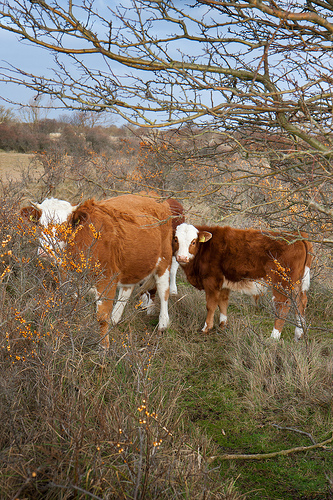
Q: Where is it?
A: This is at the field.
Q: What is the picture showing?
A: It is showing a field.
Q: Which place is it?
A: It is a field.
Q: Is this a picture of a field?
A: Yes, it is showing a field.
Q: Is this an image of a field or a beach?
A: It is showing a field.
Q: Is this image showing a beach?
A: No, the picture is showing a field.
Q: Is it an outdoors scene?
A: Yes, it is outdoors.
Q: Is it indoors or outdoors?
A: It is outdoors.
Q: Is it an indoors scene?
A: No, it is outdoors.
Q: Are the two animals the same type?
A: Yes, all the animals are cows.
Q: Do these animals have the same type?
A: Yes, all the animals are cows.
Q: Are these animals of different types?
A: No, all the animals are cows.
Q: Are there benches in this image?
A: No, there are no benches.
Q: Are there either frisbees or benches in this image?
A: No, there are no benches or frisbees.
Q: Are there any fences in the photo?
A: No, there are no fences.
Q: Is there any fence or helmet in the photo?
A: No, there are no fences or helmets.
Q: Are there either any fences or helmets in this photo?
A: No, there are no fences or helmets.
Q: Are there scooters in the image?
A: No, there are no scooters.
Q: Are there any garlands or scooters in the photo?
A: No, there are no scooters or garlands.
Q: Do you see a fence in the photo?
A: No, there are no fences.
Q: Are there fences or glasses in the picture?
A: No, there are no fences or glasses.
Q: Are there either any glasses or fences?
A: No, there are no fences or glasses.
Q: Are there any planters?
A: No, there are no planters.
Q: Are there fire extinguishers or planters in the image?
A: No, there are no planters or fire extinguishers.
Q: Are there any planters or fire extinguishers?
A: No, there are no planters or fire extinguishers.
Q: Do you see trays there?
A: No, there are no trays.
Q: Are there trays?
A: No, there are no trays.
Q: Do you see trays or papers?
A: No, there are no trays or papers.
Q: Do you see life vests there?
A: No, there are no life vests.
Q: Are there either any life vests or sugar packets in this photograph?
A: No, there are no life vests or sugar packets.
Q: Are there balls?
A: No, there are no balls.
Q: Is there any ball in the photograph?
A: No, there are no balls.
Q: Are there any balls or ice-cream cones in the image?
A: No, there are no balls or ice-cream cones.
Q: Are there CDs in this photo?
A: No, there are no cds.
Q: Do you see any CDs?
A: No, there are no cds.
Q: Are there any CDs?
A: No, there are no cds.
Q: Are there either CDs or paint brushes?
A: No, there are no CDs or paint brushes.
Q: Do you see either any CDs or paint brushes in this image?
A: No, there are no CDs or paint brushes.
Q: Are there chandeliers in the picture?
A: No, there are no chandeliers.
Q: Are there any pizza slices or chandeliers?
A: No, there are no chandeliers or pizza slices.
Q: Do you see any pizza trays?
A: No, there are no pizza trays.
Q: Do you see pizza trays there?
A: No, there are no pizza trays.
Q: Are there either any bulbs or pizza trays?
A: No, there are no pizza trays or bulbs.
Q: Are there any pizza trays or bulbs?
A: No, there are no pizza trays or bulbs.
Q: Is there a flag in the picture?
A: No, there are no flags.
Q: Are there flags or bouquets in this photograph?
A: No, there are no flags or bouquets.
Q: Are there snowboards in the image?
A: No, there are no snowboards.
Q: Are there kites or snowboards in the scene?
A: No, there are no snowboards or kites.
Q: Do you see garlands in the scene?
A: No, there are no garlands.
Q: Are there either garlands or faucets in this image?
A: No, there are no garlands or faucets.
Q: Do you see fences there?
A: No, there are no fences.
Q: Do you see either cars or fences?
A: No, there are no fences or cars.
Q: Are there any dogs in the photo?
A: No, there are no dogs.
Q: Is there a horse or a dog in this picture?
A: No, there are no dogs or horses.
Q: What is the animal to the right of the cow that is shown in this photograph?
A: The animal is a calf.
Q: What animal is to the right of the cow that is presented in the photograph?
A: The animal is a calf.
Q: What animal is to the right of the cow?
A: The animal is a calf.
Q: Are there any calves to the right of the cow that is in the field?
A: Yes, there is a calf to the right of the cow.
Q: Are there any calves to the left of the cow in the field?
A: No, the calf is to the right of the cow.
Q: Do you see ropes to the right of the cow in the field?
A: No, there is a calf to the right of the cow.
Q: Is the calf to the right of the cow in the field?
A: Yes, the calf is to the right of the cow.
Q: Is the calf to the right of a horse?
A: No, the calf is to the right of the cow.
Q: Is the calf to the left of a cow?
A: No, the calf is to the right of a cow.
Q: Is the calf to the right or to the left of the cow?
A: The calf is to the right of the cow.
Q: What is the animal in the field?
A: The animal is a calf.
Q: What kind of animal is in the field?
A: The animal is a calf.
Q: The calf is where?
A: The calf is in the field.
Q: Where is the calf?
A: The calf is in the field.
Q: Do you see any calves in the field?
A: Yes, there is a calf in the field.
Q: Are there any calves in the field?
A: Yes, there is a calf in the field.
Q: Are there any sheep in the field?
A: No, there is a calf in the field.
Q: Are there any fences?
A: No, there are no fences.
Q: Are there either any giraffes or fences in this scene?
A: No, there are no fences or giraffes.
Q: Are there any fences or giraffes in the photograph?
A: No, there are no fences or giraffes.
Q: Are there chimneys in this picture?
A: No, there are no chimneys.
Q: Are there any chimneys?
A: No, there are no chimneys.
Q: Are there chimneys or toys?
A: No, there are no chimneys or toys.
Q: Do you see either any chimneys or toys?
A: No, there are no chimneys or toys.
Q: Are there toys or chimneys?
A: No, there are no chimneys or toys.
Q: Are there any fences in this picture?
A: No, there are no fences.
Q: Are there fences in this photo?
A: No, there are no fences.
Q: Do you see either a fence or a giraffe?
A: No, there are no fences or giraffes.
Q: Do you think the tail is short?
A: Yes, the tail is short.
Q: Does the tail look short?
A: Yes, the tail is short.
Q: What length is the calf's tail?
A: The tail is short.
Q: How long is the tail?
A: The tail is short.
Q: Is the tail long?
A: No, the tail is short.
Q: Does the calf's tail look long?
A: No, the tail is short.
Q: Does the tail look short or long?
A: The tail is short.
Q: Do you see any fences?
A: No, there are no fences.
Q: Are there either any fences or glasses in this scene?
A: No, there are no fences or glasses.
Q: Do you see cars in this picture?
A: No, there are no cars.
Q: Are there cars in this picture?
A: No, there are no cars.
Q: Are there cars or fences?
A: No, there are no cars or fences.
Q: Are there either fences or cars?
A: No, there are no cars or fences.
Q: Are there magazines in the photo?
A: No, there are no magazines.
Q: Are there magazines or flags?
A: No, there are no magazines or flags.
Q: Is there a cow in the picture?
A: Yes, there is a cow.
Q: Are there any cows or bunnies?
A: Yes, there is a cow.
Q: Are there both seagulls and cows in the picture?
A: No, there is a cow but no seagulls.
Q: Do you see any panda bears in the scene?
A: No, there are no panda bears.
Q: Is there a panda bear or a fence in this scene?
A: No, there are no panda bears or fences.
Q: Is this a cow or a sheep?
A: This is a cow.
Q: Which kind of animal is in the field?
A: The animal is a cow.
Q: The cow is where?
A: The cow is in the field.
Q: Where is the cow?
A: The cow is in the field.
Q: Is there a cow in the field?
A: Yes, there is a cow in the field.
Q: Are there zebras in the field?
A: No, there is a cow in the field.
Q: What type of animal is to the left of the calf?
A: The animal is a cow.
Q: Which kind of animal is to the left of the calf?
A: The animal is a cow.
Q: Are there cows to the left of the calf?
A: Yes, there is a cow to the left of the calf.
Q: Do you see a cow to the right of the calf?
A: No, the cow is to the left of the calf.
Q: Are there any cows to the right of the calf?
A: No, the cow is to the left of the calf.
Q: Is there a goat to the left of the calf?
A: No, there is a cow to the left of the calf.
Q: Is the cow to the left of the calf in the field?
A: Yes, the cow is to the left of the calf.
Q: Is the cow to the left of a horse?
A: No, the cow is to the left of the calf.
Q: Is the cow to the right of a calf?
A: No, the cow is to the left of a calf.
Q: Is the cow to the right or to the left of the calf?
A: The cow is to the left of the calf.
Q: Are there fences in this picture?
A: No, there are no fences.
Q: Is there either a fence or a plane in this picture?
A: No, there are no fences or airplanes.